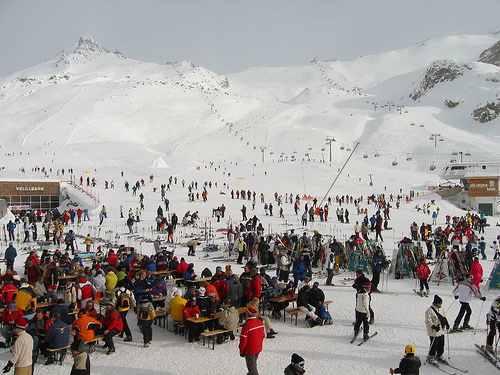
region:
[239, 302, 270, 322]
the head of a man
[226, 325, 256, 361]
the arm of a man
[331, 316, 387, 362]
the legs of a man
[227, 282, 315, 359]
a man wearing a coat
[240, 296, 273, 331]
a man wearing a hat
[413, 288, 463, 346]
a man wearing a white coat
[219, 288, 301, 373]
a man wearing red coat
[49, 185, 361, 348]
lots of people in the snow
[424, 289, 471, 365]
a man on skis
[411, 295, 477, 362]
a man holding ski stick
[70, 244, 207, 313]
People outside in the snow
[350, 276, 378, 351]
Person on skis outside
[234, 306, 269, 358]
Person wearing a red coat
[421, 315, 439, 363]
Ski pole in a person's hand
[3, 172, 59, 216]
Brick building in the snow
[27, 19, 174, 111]
Large mountain covered with snows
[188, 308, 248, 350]
Picnic table outside in the snow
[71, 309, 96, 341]
Person wearing an orange jacket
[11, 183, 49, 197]
Wtiting on the front of a building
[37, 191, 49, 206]
Window in the front of the building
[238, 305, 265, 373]
A man in a red jacket.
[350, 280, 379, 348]
A man skiing.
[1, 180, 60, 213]
A small building.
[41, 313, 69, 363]
A man sitting down.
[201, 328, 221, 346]
Part of a bench.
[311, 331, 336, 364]
Part of the snow.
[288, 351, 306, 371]
The head of a person.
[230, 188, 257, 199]
A group of people in the snow.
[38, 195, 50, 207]
Windows on the building.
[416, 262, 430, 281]
A red jacket.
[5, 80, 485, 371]
People outside at a ski slope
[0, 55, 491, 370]
Crowd of people at a ski slope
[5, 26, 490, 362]
Crowd of people gathering on ski slope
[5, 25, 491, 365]
Crowd of skiers climbing and walking down slope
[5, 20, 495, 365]
A winter day on a ski slope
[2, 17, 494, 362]
A ski slope crowded with dozens of people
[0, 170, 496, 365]
A variety of people wearing winter outfits on ski slope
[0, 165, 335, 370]
A crowd of people sitting at tables in the middle of winter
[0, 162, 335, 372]
A crowd of people sitting and talking near ski slopes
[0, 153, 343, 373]
A crowd of people walking towards table and ski slopes during the winter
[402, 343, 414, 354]
Yellow helmet on a head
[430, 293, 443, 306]
Black winter hat on a head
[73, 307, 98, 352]
A man wearing an orange jacket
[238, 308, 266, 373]
Man wearing a red jacket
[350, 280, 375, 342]
A skiier wearing a white jacket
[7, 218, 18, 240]
A person wearing a blue jacket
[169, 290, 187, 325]
A person wearing a yellow jacket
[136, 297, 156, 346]
Person wearing a yellow and gray jacket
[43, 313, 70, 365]
Person wearing a navy blue jacket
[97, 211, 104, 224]
person wearing a light blue jacket